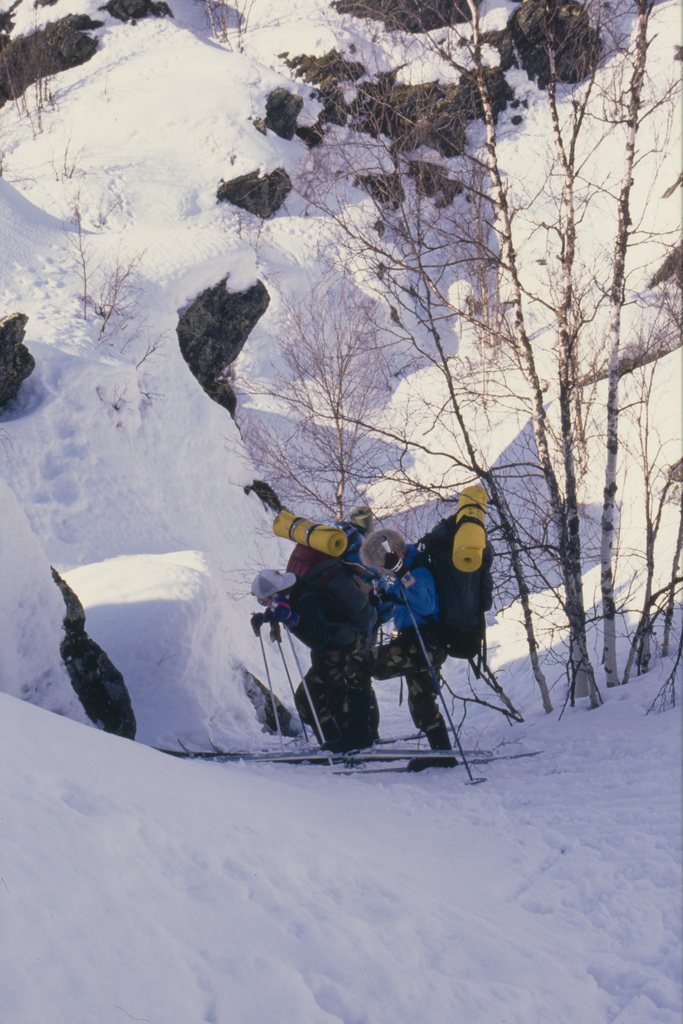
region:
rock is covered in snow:
[182, 270, 273, 390]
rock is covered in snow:
[52, 567, 137, 737]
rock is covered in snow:
[243, 671, 299, 739]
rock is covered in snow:
[1, 308, 33, 409]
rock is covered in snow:
[218, 167, 291, 220]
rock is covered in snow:
[363, 172, 405, 211]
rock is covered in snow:
[285, 52, 511, 156]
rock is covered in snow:
[1, 1, 172, 98]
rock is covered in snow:
[499, 1, 598, 85]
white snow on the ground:
[347, 824, 466, 966]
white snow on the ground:
[540, 818, 639, 976]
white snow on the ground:
[161, 891, 215, 976]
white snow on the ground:
[64, 840, 218, 1017]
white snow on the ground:
[101, 496, 208, 730]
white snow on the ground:
[111, 323, 179, 479]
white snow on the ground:
[321, 247, 469, 444]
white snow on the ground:
[44, 178, 192, 488]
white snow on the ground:
[339, 815, 579, 1015]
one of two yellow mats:
[269, 502, 350, 558]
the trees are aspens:
[301, 0, 681, 737]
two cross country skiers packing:
[150, 476, 552, 783]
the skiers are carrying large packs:
[262, 483, 503, 682]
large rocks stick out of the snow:
[2, 4, 612, 438]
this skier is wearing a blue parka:
[359, 528, 464, 773]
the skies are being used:
[147, 717, 548, 779]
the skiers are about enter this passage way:
[10, 485, 225, 758]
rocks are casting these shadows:
[229, 402, 627, 639]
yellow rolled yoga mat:
[452, 482, 490, 600]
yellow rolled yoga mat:
[273, 502, 351, 555]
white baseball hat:
[243, 563, 305, 598]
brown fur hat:
[363, 528, 408, 573]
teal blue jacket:
[372, 554, 452, 626]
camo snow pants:
[370, 626, 458, 751]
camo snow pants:
[289, 622, 382, 751]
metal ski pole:
[401, 595, 477, 792]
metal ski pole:
[279, 614, 328, 782]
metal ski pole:
[261, 607, 307, 746]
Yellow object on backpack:
[445, 481, 493, 581]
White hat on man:
[239, 558, 298, 600]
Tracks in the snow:
[533, 742, 647, 830]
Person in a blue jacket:
[352, 523, 464, 773]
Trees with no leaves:
[277, 282, 396, 546]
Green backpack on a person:
[417, 518, 497, 677]